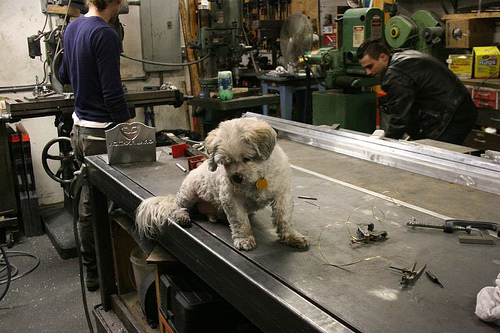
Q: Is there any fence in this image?
A: No, there are no fences.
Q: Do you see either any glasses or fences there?
A: No, there are no fences or glasses.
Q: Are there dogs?
A: Yes, there is a dog.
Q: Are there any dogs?
A: Yes, there is a dog.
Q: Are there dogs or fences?
A: Yes, there is a dog.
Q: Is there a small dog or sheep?
A: Yes, there is a small dog.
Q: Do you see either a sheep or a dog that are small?
A: Yes, the dog is small.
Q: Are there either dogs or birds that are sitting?
A: Yes, the dog is sitting.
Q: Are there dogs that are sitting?
A: Yes, there is a dog that is sitting.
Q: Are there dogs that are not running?
A: Yes, there is a dog that is sitting.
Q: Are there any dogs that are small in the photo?
A: Yes, there is a small dog.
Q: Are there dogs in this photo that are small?
A: Yes, there is a small dog.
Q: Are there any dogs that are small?
A: Yes, there is a dog that is small.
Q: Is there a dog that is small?
A: Yes, there is a dog that is small.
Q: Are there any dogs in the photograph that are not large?
A: Yes, there is a small dog.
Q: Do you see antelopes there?
A: No, there are no antelopes.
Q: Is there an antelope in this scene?
A: No, there are no antelopes.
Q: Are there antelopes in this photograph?
A: No, there are no antelopes.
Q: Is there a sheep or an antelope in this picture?
A: No, there are no antelopes or sheep.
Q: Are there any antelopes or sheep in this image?
A: No, there are no antelopes or sheep.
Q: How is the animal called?
A: The animal is a dog.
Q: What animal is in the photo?
A: The animal is a dog.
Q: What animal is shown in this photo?
A: The animal is a dog.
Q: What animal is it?
A: The animal is a dog.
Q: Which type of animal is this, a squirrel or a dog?
A: This is a dog.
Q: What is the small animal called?
A: The animal is a dog.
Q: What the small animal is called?
A: The animal is a dog.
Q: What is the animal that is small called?
A: The animal is a dog.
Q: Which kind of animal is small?
A: The animal is a dog.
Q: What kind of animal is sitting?
A: The animal is a dog.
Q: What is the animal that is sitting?
A: The animal is a dog.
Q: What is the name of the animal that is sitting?
A: The animal is a dog.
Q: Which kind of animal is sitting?
A: The animal is a dog.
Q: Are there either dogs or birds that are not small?
A: No, there is a dog but it is small.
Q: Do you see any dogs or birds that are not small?
A: No, there is a dog but it is small.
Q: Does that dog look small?
A: Yes, the dog is small.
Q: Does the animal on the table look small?
A: Yes, the dog is small.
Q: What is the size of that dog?
A: The dog is small.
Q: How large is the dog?
A: The dog is small.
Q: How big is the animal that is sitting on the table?
A: The dog is small.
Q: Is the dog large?
A: No, the dog is small.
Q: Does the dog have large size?
A: No, the dog is small.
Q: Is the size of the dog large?
A: No, the dog is small.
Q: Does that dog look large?
A: No, the dog is small.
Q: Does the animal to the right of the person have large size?
A: No, the dog is small.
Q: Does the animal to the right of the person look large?
A: No, the dog is small.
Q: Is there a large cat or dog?
A: No, there is a dog but it is small.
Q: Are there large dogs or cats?
A: No, there is a dog but it is small.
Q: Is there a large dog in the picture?
A: No, there is a dog but it is small.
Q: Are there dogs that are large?
A: No, there is a dog but it is small.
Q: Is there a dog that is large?
A: No, there is a dog but it is small.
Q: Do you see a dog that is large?
A: No, there is a dog but it is small.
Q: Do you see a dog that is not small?
A: No, there is a dog but it is small.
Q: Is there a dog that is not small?
A: No, there is a dog but it is small.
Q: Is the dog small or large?
A: The dog is small.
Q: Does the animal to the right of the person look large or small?
A: The dog is small.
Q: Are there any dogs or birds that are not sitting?
A: No, there is a dog but it is sitting.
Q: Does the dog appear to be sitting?
A: Yes, the dog is sitting.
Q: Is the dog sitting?
A: Yes, the dog is sitting.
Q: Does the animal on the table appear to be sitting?
A: Yes, the dog is sitting.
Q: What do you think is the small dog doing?
A: The dog is sitting.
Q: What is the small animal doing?
A: The dog is sitting.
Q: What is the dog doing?
A: The dog is sitting.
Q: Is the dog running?
A: No, the dog is sitting.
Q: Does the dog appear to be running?
A: No, the dog is sitting.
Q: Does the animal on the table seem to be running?
A: No, the dog is sitting.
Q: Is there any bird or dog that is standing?
A: No, there is a dog but it is sitting.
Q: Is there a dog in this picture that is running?
A: No, there is a dog but it is sitting.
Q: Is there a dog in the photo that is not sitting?
A: No, there is a dog but it is sitting.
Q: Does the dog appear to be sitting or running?
A: The dog is sitting.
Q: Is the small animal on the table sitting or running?
A: The dog is sitting.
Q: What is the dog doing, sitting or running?
A: The dog is sitting.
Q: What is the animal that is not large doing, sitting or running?
A: The dog is sitting.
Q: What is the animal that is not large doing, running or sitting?
A: The dog is sitting.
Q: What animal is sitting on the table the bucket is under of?
A: The dog is sitting on the table.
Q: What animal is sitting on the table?
A: The dog is sitting on the table.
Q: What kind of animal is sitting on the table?
A: The animal is a dog.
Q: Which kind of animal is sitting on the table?
A: The animal is a dog.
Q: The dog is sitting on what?
A: The dog is sitting on the table.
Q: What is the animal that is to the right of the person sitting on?
A: The dog is sitting on the table.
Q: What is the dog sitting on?
A: The dog is sitting on the table.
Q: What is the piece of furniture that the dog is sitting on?
A: The piece of furniture is a table.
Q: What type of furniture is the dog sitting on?
A: The dog is sitting on the table.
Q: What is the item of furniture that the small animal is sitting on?
A: The piece of furniture is a table.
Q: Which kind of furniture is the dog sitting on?
A: The dog is sitting on the table.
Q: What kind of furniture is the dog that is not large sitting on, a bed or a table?
A: The dog is sitting on a table.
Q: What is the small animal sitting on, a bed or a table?
A: The dog is sitting on a table.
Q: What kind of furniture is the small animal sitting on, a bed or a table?
A: The dog is sitting on a table.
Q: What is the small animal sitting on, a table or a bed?
A: The dog is sitting on a table.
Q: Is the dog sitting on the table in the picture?
A: Yes, the dog is sitting on the table.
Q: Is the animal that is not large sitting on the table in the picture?
A: Yes, the dog is sitting on the table.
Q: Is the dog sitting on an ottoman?
A: No, the dog is sitting on the table.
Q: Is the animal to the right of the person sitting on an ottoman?
A: No, the dog is sitting on the table.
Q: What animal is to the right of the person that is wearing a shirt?
A: The animal is a dog.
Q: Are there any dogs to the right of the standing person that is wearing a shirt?
A: Yes, there is a dog to the right of the person.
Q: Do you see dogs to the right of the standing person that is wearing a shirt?
A: Yes, there is a dog to the right of the person.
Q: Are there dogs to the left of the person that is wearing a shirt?
A: No, the dog is to the right of the person.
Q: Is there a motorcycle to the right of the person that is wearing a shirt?
A: No, there is a dog to the right of the person.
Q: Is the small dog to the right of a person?
A: Yes, the dog is to the right of a person.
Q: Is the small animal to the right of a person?
A: Yes, the dog is to the right of a person.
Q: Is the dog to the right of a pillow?
A: No, the dog is to the right of a person.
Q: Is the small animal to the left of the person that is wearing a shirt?
A: No, the dog is to the right of the person.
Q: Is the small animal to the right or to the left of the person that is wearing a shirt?
A: The dog is to the right of the person.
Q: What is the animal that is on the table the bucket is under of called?
A: The animal is a dog.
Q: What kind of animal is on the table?
A: The animal is a dog.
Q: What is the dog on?
A: The dog is on the table.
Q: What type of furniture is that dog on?
A: The dog is on the table.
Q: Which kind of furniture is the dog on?
A: The dog is on the table.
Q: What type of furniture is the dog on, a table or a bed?
A: The dog is on a table.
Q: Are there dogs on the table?
A: Yes, there is a dog on the table.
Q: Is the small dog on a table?
A: Yes, the dog is on a table.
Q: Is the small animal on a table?
A: Yes, the dog is on a table.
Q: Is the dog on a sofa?
A: No, the dog is on a table.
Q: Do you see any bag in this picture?
A: No, there are no bags.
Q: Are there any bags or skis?
A: No, there are no bags or skis.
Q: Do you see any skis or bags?
A: No, there are no bags or skis.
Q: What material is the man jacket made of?
A: The jacket is made of leather.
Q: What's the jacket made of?
A: The jacket is made of leather.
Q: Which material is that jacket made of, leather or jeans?
A: The jacket is made of leather.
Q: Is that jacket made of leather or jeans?
A: The jacket is made of leather.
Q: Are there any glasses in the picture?
A: No, there are no glasses.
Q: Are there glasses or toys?
A: No, there are no glasses or toys.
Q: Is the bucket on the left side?
A: Yes, the bucket is on the left of the image.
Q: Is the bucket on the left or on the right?
A: The bucket is on the left of the image.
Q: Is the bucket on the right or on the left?
A: The bucket is on the left of the image.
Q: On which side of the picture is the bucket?
A: The bucket is on the left of the image.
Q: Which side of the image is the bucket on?
A: The bucket is on the left of the image.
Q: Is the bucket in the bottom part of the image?
A: Yes, the bucket is in the bottom of the image.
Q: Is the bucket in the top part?
A: No, the bucket is in the bottom of the image.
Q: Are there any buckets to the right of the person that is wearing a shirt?
A: Yes, there is a bucket to the right of the person.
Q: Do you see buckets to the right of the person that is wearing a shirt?
A: Yes, there is a bucket to the right of the person.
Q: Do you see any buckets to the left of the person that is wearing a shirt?
A: No, the bucket is to the right of the person.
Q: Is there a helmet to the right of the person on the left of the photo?
A: No, there is a bucket to the right of the person.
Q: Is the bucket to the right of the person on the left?
A: Yes, the bucket is to the right of the person.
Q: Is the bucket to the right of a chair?
A: No, the bucket is to the right of the person.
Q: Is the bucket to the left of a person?
A: No, the bucket is to the right of a person.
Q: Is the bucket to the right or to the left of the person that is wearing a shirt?
A: The bucket is to the right of the person.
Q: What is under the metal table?
A: The bucket is under the table.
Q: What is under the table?
A: The bucket is under the table.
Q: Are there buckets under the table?
A: Yes, there is a bucket under the table.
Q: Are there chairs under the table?
A: No, there is a bucket under the table.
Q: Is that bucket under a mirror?
A: No, the bucket is under the table.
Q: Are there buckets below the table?
A: Yes, there is a bucket below the table.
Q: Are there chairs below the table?
A: No, there is a bucket below the table.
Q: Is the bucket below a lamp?
A: No, the bucket is below a table.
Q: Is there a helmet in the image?
A: No, there are no helmets.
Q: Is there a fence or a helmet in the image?
A: No, there are no helmets or fences.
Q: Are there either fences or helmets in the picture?
A: No, there are no helmets or fences.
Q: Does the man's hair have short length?
A: Yes, the hair is short.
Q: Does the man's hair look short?
A: Yes, the hair is short.